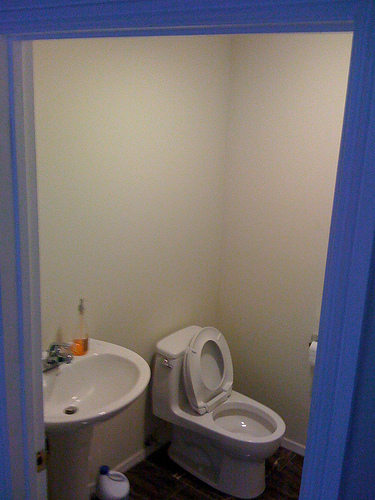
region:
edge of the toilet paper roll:
[304, 332, 323, 363]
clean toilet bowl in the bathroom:
[206, 396, 285, 452]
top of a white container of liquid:
[93, 458, 133, 497]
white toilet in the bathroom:
[147, 323, 282, 494]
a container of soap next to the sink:
[71, 291, 88, 355]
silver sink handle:
[43, 336, 72, 371]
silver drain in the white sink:
[64, 399, 76, 420]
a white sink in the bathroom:
[12, 334, 149, 494]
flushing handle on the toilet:
[160, 356, 175, 369]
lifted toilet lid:
[178, 324, 238, 408]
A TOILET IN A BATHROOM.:
[140, 313, 295, 497]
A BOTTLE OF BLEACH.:
[98, 461, 136, 493]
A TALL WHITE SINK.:
[43, 328, 148, 499]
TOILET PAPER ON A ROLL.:
[300, 330, 325, 362]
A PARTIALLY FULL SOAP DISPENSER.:
[63, 294, 103, 357]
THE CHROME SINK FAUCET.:
[40, 336, 79, 376]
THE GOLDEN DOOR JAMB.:
[35, 445, 48, 473]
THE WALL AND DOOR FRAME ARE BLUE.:
[313, 272, 343, 499]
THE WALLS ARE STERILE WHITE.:
[225, 224, 303, 310]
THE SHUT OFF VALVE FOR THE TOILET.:
[142, 425, 164, 453]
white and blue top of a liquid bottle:
[93, 463, 135, 497]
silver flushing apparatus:
[158, 355, 174, 368]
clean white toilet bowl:
[214, 398, 277, 448]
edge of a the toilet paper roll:
[303, 335, 321, 361]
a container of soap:
[71, 293, 88, 355]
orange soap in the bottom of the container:
[70, 333, 92, 356]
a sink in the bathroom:
[28, 321, 150, 456]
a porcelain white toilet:
[148, 314, 283, 492]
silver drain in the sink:
[63, 399, 78, 414]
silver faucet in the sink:
[46, 339, 71, 371]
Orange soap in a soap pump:
[70, 296, 92, 356]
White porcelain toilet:
[149, 324, 287, 497]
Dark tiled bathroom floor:
[85, 436, 306, 498]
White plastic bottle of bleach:
[94, 461, 132, 496]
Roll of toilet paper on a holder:
[305, 331, 320, 366]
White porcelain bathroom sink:
[41, 336, 151, 498]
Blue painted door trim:
[2, 0, 373, 498]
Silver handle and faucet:
[40, 340, 74, 372]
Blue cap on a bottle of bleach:
[95, 463, 110, 476]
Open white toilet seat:
[180, 324, 236, 416]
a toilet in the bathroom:
[143, 313, 291, 499]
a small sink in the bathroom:
[42, 326, 140, 498]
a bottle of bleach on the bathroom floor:
[95, 458, 135, 498]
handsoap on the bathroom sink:
[69, 286, 99, 361]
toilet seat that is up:
[178, 323, 242, 413]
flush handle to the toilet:
[159, 354, 175, 370]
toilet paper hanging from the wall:
[302, 328, 317, 365]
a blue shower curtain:
[317, 26, 372, 495]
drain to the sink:
[57, 399, 80, 416]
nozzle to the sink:
[42, 339, 70, 377]